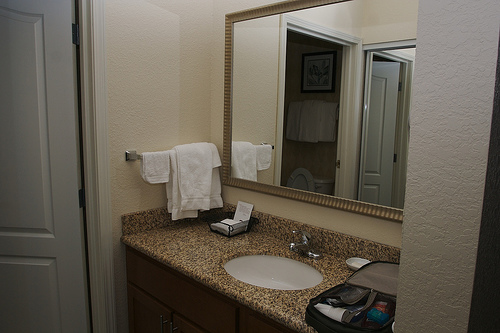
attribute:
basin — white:
[211, 237, 342, 327]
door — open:
[8, 7, 133, 331]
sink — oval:
[223, 250, 325, 289]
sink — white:
[219, 249, 324, 299]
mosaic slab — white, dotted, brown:
[150, 225, 217, 262]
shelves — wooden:
[123, 242, 299, 332]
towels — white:
[159, 146, 211, 210]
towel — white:
[142, 143, 224, 223]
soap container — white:
[344, 254, 371, 270]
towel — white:
[175, 142, 215, 216]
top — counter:
[159, 227, 314, 315]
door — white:
[0, 8, 82, 331]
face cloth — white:
[140, 151, 172, 183]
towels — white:
[170, 154, 227, 211]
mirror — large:
[228, 12, 397, 205]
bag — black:
[303, 257, 398, 331]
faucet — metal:
[286, 227, 323, 257]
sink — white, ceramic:
[226, 246, 334, 299]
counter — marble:
[151, 213, 343, 330]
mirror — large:
[230, 0, 417, 210]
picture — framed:
[299, 48, 339, 94]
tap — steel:
[283, 220, 313, 255]